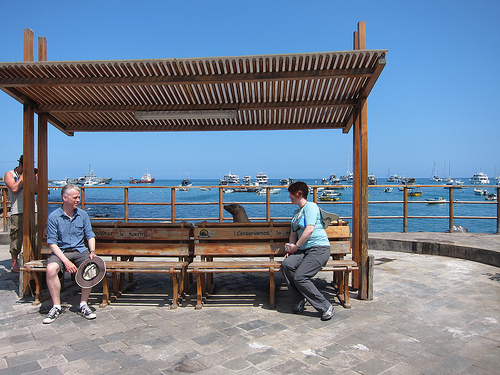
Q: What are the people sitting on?
A: A bench.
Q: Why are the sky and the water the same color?
A: The sky is the refection of the water.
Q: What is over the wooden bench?
A: A large wooden cover.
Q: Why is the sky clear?
A: There's no cloads.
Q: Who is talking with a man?
A: A woman.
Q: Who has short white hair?
A: A man.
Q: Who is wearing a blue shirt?
A: A man.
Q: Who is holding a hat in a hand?
A: A man.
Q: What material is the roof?
A: Wood.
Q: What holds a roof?
A: Four poles.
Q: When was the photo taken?
A: Daytime.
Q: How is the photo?
A: Clear.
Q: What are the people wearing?
A: Clothes.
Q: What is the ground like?
A: Clean.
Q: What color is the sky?
A: Blue.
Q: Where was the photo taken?
A: A pier.